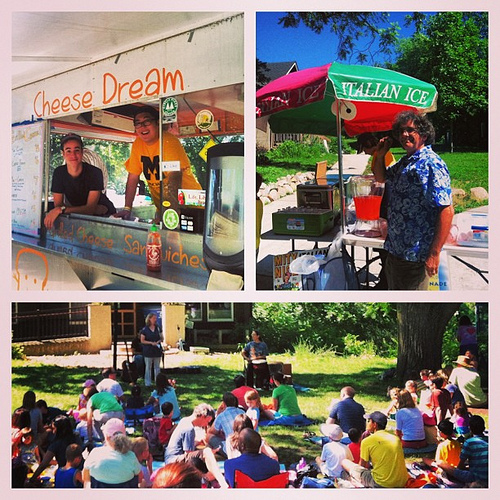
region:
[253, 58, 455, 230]
A green, red and pink Italian Ice umbrella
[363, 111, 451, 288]
Man in a blue and white decorated shirt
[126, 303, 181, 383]
Woman speaking outdoors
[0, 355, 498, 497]
Crowd of people sitting and listening to a speaker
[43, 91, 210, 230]
Two guys looking out of a food truck window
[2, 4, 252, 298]
A food truck called Cheese Dream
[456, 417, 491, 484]
Person sitting in a blue striped shirt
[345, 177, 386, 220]
A glass container with red Italian Ice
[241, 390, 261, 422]
A child turning around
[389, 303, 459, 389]
A large brown tree trunk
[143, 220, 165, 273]
bottle of hot sauce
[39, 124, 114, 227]
man wearing a black shirt and a hat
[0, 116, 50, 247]
dry erase board with lots of words on it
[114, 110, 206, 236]
man wearing glasses and a yellow shirt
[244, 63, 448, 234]
red and green umbrella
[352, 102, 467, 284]
old man wearing a blue and white floral printed shirt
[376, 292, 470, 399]
very large tree trunk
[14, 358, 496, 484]
large group of people sitting on grass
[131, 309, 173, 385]
woman wearing a blue shirt standing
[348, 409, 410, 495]
man wearing a hat and yellow shirt sitting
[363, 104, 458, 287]
man is under an umbrella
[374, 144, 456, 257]
man is wearing a blue shirt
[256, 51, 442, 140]
umbrella reads italian ice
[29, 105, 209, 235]
two young men are in a truck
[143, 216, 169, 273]
bottle is on the counter of truck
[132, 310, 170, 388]
woman is speaking into a microphone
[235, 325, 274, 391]
woman is playing a drum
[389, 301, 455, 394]
large tree is to the right of the crowd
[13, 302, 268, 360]
building in the background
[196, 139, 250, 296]
napkin dispenser on truck counter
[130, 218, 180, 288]
a bottle of hot sauce sitting on the counter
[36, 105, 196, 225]
a pair of boys working a food truck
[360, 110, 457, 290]
a man in a blue Hawaiian shirt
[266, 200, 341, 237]
a green cooler filled with bottled water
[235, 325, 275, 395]
a woman playing a bongo drum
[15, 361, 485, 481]
a crowd of people sitting on the grass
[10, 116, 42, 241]
a menu board on the counter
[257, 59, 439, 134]
an Italian ice umbrella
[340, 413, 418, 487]
a man in a yellow t-shirt sitting cross-legged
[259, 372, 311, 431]
a woman in a green shirt sitting cross-legged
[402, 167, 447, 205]
man wearing blue and white shirt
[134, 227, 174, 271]
red soda bottle on counter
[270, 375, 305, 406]
woman wearing green shirt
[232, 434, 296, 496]
man sitting on red pillow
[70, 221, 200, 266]
writing on side of food truck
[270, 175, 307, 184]
stone pavement on walkway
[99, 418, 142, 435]
pink hat on man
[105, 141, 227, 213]
man wearing orange shirt with black words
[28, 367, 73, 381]
well manicured green grass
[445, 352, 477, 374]
man wearing tan hat